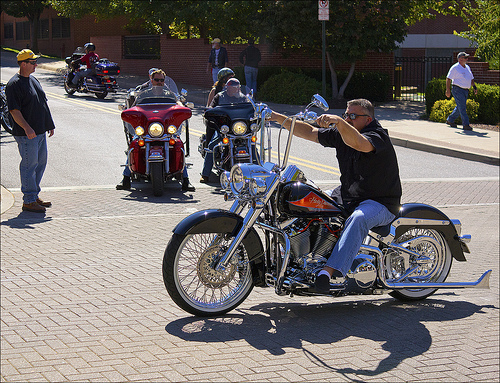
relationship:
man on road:
[19, 50, 50, 160] [0, 121, 110, 264]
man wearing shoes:
[264, 98, 404, 292] [306, 271, 333, 296]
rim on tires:
[176, 240, 245, 310] [171, 207, 456, 330]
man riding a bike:
[291, 91, 416, 294] [160, 89, 491, 318]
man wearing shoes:
[264, 98, 404, 292] [297, 274, 338, 300]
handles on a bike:
[246, 87, 337, 189] [153, 97, 478, 295]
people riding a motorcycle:
[126, 67, 190, 99] [120, 95, 192, 202]